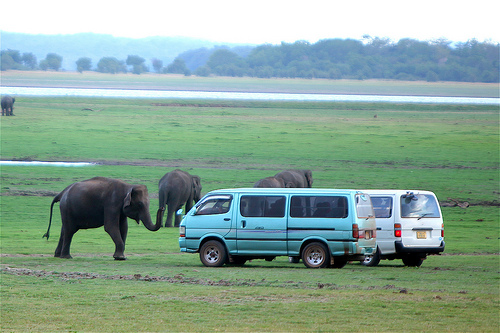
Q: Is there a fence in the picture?
A: No, there are no fences.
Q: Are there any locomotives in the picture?
A: No, there are no locomotives.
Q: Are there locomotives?
A: No, there are no locomotives.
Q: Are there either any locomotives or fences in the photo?
A: No, there are no locomotives or fences.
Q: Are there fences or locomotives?
A: No, there are no locomotives or fences.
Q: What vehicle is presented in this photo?
A: The vehicle is a van.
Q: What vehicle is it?
A: The vehicle is a van.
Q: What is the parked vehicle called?
A: The vehicle is a van.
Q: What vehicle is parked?
A: The vehicle is a van.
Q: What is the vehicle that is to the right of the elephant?
A: The vehicle is a van.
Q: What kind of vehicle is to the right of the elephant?
A: The vehicle is a van.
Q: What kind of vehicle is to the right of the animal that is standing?
A: The vehicle is a van.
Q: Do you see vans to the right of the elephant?
A: Yes, there is a van to the right of the elephant.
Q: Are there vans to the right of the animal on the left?
A: Yes, there is a van to the right of the elephant.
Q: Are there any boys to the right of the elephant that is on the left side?
A: No, there is a van to the right of the elephant.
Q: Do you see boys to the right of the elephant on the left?
A: No, there is a van to the right of the elephant.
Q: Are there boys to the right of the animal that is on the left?
A: No, there is a van to the right of the elephant.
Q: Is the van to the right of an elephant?
A: Yes, the van is to the right of an elephant.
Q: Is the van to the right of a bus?
A: No, the van is to the right of an elephant.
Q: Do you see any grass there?
A: Yes, there is grass.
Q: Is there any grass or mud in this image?
A: Yes, there is grass.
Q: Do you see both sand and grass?
A: No, there is grass but no sand.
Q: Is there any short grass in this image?
A: Yes, there is short grass.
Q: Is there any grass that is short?
A: Yes, there is grass that is short.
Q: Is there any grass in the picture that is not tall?
A: Yes, there is short grass.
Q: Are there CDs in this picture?
A: No, there are no cds.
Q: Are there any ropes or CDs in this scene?
A: No, there are no CDs or ropes.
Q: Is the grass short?
A: Yes, the grass is short.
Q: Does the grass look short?
A: Yes, the grass is short.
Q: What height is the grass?
A: The grass is short.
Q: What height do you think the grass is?
A: The grass is short.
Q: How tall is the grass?
A: The grass is short.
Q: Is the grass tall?
A: No, the grass is short.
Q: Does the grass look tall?
A: No, the grass is short.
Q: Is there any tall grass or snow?
A: No, there is grass but it is short.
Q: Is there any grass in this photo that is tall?
A: No, there is grass but it is short.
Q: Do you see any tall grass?
A: No, there is grass but it is short.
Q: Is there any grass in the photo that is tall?
A: No, there is grass but it is short.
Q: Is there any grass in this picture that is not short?
A: No, there is grass but it is short.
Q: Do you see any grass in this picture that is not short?
A: No, there is grass but it is short.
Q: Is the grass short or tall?
A: The grass is short.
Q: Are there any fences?
A: No, there are no fences.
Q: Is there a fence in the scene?
A: No, there are no fences.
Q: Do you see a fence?
A: No, there are no fences.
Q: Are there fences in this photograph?
A: No, there are no fences.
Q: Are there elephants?
A: Yes, there is an elephant.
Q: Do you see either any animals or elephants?
A: Yes, there is an elephant.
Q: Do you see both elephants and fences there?
A: No, there is an elephant but no fences.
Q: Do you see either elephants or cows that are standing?
A: Yes, the elephant is standing.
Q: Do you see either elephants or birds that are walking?
A: Yes, the elephant is walking.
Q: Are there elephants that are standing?
A: Yes, there is an elephant that is standing.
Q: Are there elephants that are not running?
A: Yes, there is an elephant that is standing.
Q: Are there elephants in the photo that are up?
A: Yes, there is an elephant that is up.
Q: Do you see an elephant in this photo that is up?
A: Yes, there is an elephant that is up.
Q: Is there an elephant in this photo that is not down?
A: Yes, there is an elephant that is up.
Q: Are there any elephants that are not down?
A: Yes, there is an elephant that is up.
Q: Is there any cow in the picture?
A: No, there are no cows.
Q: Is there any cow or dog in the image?
A: No, there are no cows or dogs.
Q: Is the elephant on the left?
A: Yes, the elephant is on the left of the image.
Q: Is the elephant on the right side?
A: No, the elephant is on the left of the image.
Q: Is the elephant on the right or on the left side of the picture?
A: The elephant is on the left of the image.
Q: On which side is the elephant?
A: The elephant is on the left of the image.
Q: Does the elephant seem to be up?
A: Yes, the elephant is up.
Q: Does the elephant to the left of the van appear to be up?
A: Yes, the elephant is up.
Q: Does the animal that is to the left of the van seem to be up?
A: Yes, the elephant is up.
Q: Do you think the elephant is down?
A: No, the elephant is up.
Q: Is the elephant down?
A: No, the elephant is up.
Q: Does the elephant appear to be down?
A: No, the elephant is up.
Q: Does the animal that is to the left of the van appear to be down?
A: No, the elephant is up.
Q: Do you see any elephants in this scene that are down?
A: No, there is an elephant but it is up.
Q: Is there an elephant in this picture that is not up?
A: No, there is an elephant but it is up.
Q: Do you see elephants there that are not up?
A: No, there is an elephant but it is up.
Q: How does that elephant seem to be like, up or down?
A: The elephant is up.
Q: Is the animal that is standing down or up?
A: The elephant is up.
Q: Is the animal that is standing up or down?
A: The elephant is up.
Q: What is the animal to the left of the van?
A: The animal is an elephant.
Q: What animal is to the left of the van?
A: The animal is an elephant.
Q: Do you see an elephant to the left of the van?
A: Yes, there is an elephant to the left of the van.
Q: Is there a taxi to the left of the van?
A: No, there is an elephant to the left of the van.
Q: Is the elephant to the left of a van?
A: Yes, the elephant is to the left of a van.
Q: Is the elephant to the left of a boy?
A: No, the elephant is to the left of a van.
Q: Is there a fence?
A: No, there are no fences.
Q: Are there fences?
A: No, there are no fences.